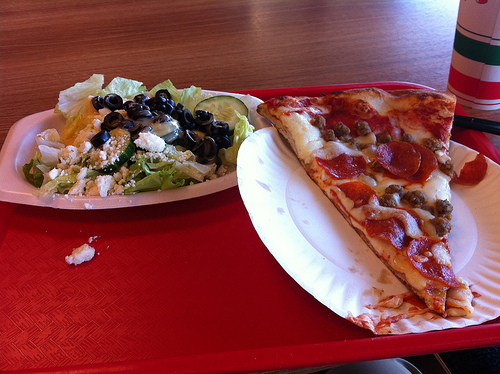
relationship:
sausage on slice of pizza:
[375, 191, 399, 210] [256, 87, 475, 322]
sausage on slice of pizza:
[311, 108, 326, 130] [256, 87, 475, 322]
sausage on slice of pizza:
[355, 119, 370, 140] [256, 87, 475, 322]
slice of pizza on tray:
[256, 87, 475, 322] [3, 80, 500, 374]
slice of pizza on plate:
[256, 87, 475, 322] [236, 127, 498, 336]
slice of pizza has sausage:
[256, 87, 475, 322] [375, 191, 399, 210]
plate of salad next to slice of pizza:
[1, 73, 276, 216] [256, 87, 475, 322]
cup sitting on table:
[445, 2, 499, 113] [1, 1, 499, 153]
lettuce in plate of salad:
[52, 71, 106, 120] [1, 73, 276, 216]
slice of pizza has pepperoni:
[256, 87, 475, 322] [378, 138, 440, 184]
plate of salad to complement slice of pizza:
[1, 73, 276, 216] [256, 87, 475, 322]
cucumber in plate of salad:
[191, 92, 249, 122] [1, 73, 276, 216]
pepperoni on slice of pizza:
[378, 138, 440, 184] [256, 87, 475, 322]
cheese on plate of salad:
[134, 130, 166, 156] [1, 73, 276, 216]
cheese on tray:
[64, 241, 98, 269] [3, 80, 500, 374]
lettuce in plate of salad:
[152, 77, 210, 116] [1, 73, 276, 216]